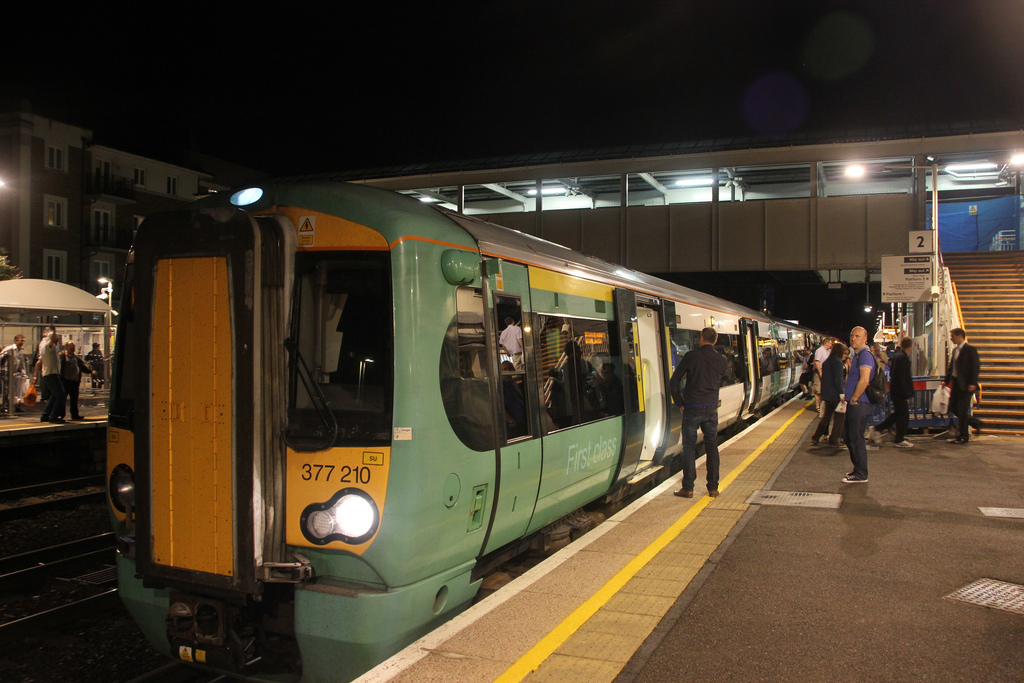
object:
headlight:
[336, 494, 372, 539]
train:
[107, 182, 847, 682]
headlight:
[117, 463, 136, 510]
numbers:
[301, 464, 370, 485]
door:
[142, 255, 243, 599]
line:
[353, 386, 822, 682]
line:
[529, 266, 614, 303]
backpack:
[857, 349, 887, 403]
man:
[841, 326, 888, 482]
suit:
[944, 342, 980, 439]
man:
[941, 328, 987, 445]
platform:
[342, 385, 1023, 682]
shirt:
[844, 348, 879, 403]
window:
[536, 312, 577, 435]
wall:
[928, 190, 1024, 251]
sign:
[907, 230, 931, 254]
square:
[941, 576, 1024, 614]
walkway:
[279, 120, 1024, 273]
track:
[0, 529, 139, 632]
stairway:
[944, 250, 1024, 435]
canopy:
[0, 277, 109, 312]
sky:
[0, 0, 1022, 148]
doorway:
[636, 303, 661, 474]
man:
[670, 328, 728, 498]